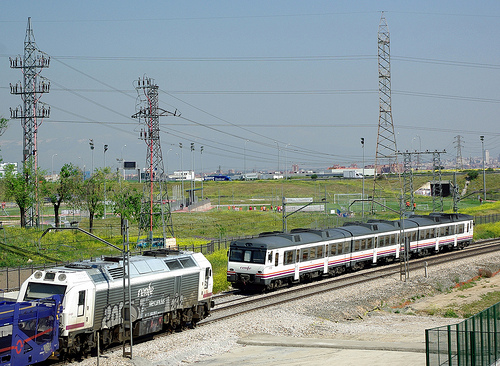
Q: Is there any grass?
A: Yes, there is grass.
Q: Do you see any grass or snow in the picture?
A: Yes, there is grass.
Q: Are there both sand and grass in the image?
A: No, there is grass but no sand.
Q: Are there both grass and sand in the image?
A: No, there is grass but no sand.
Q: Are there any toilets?
A: No, there are no toilets.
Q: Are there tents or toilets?
A: No, there are no toilets or tents.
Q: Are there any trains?
A: Yes, there are trains.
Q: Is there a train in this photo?
A: Yes, there are trains.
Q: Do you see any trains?
A: Yes, there are trains.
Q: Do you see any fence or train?
A: Yes, there are trains.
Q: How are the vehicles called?
A: The vehicles are trains.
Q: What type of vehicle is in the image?
A: The vehicle is trains.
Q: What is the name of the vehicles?
A: The vehicles are trains.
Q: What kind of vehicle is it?
A: The vehicles are trains.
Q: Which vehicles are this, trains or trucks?
A: Those are trains.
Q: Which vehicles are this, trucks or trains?
A: Those are trains.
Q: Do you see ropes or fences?
A: Yes, there is a fence.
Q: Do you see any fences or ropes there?
A: Yes, there is a fence.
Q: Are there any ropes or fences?
A: Yes, there is a fence.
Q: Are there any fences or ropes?
A: Yes, there is a fence.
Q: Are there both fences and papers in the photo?
A: No, there is a fence but no papers.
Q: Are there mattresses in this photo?
A: No, there are no mattresses.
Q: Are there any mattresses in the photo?
A: No, there are no mattresses.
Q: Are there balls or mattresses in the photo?
A: No, there are no mattresses or balls.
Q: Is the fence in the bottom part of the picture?
A: Yes, the fence is in the bottom of the image.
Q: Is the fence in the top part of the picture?
A: No, the fence is in the bottom of the image.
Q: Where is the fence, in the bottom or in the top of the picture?
A: The fence is in the bottom of the image.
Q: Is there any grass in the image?
A: Yes, there is grass.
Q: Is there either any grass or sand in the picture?
A: Yes, there is grass.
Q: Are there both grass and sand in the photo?
A: No, there is grass but no sand.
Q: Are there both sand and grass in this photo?
A: No, there is grass but no sand.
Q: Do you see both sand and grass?
A: No, there is grass but no sand.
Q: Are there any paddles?
A: No, there are no paddles.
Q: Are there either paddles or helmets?
A: No, there are no paddles or helmets.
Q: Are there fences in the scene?
A: Yes, there is a fence.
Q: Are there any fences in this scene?
A: Yes, there is a fence.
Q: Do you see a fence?
A: Yes, there is a fence.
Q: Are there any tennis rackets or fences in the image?
A: Yes, there is a fence.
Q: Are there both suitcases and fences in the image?
A: No, there is a fence but no suitcases.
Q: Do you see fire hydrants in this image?
A: No, there are no fire hydrants.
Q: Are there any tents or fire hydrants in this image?
A: No, there are no fire hydrants or tents.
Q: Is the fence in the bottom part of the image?
A: Yes, the fence is in the bottom of the image.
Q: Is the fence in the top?
A: No, the fence is in the bottom of the image.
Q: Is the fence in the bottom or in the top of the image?
A: The fence is in the bottom of the image.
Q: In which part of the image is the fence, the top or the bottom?
A: The fence is in the bottom of the image.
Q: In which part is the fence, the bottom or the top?
A: The fence is in the bottom of the image.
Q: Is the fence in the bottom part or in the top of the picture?
A: The fence is in the bottom of the image.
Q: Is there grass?
A: Yes, there is grass.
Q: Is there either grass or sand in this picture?
A: Yes, there is grass.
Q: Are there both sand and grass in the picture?
A: No, there is grass but no sand.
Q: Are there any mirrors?
A: No, there are no mirrors.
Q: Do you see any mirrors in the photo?
A: No, there are no mirrors.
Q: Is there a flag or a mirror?
A: No, there are no mirrors or flags.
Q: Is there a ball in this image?
A: No, there are no balls.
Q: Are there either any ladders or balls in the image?
A: No, there are no balls or ladders.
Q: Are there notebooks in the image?
A: No, there are no notebooks.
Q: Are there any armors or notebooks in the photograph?
A: No, there are no notebooks or armors.